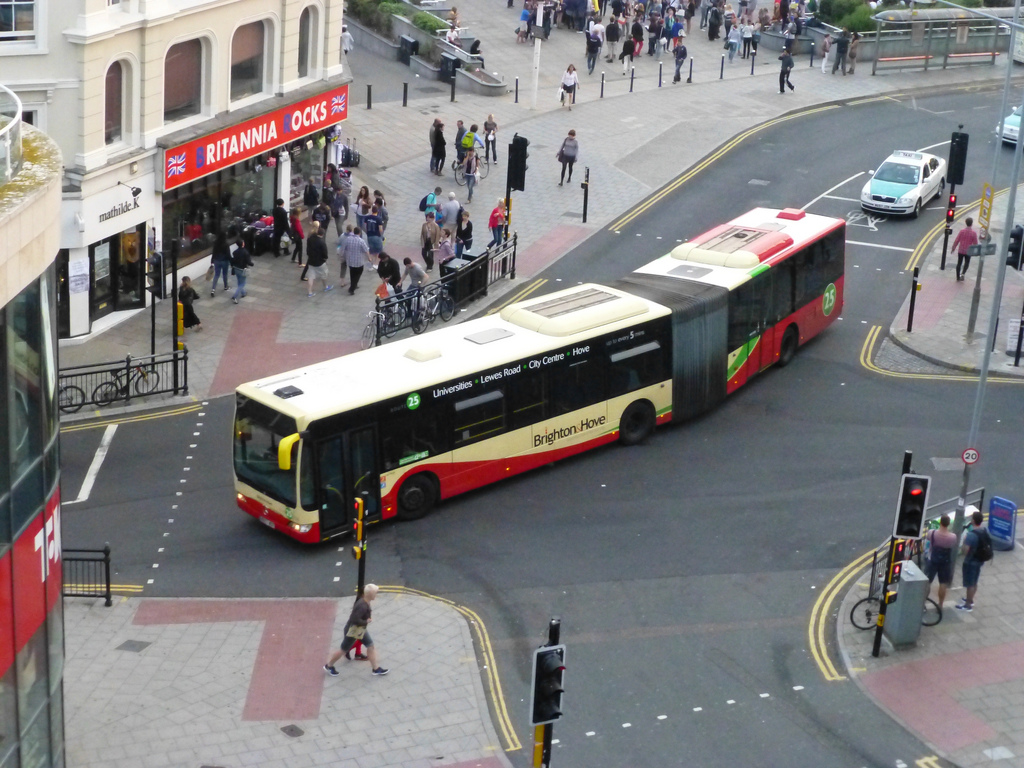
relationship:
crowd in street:
[520, 0, 1017, 72] [546, 0, 791, 89]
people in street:
[529, 0, 810, 76] [546, 0, 791, 89]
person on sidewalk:
[319, 571, 395, 699] [114, 571, 506, 764]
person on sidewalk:
[939, 513, 1000, 602] [822, 486, 1021, 720]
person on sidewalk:
[269, 186, 291, 256] [131, 150, 440, 356]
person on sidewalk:
[348, 173, 403, 243] [87, 2, 1010, 411]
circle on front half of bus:
[401, 389, 425, 413] [226, 202, 844, 552]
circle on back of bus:
[405, 385, 431, 407] [226, 202, 844, 552]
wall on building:
[3, 369, 118, 761] [15, 177, 109, 763]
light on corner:
[865, 438, 937, 607] [810, 434, 971, 724]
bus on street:
[204, 155, 868, 579] [126, 224, 984, 752]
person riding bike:
[443, 97, 532, 197] [433, 83, 539, 220]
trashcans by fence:
[432, 245, 489, 306] [372, 240, 541, 355]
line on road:
[108, 390, 206, 565] [26, 405, 260, 552]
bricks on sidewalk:
[127, 584, 354, 729] [61, 586, 485, 762]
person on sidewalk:
[516, 85, 631, 235] [382, 52, 737, 269]